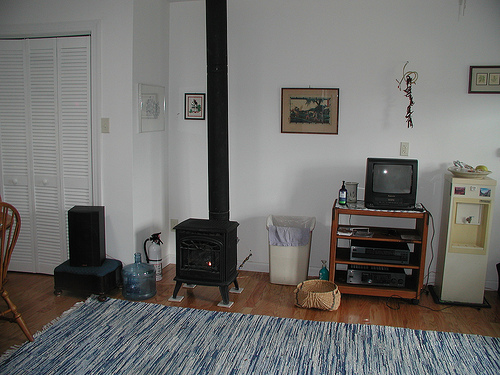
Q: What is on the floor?
A: A rug.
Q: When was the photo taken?
A: Daytime.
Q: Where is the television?
A: On the stand.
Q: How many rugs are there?
A: One.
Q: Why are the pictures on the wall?
A: For decoration.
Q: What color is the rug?
A: Blue.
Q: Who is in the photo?
A: Nobody.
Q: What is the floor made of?
A: Wood.